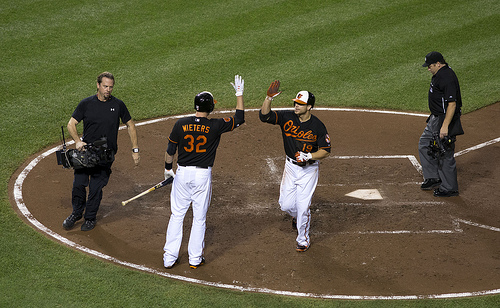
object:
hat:
[192, 91, 218, 112]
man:
[159, 74, 247, 269]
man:
[259, 79, 332, 252]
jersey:
[165, 109, 246, 167]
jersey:
[259, 109, 332, 163]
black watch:
[132, 146, 140, 153]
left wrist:
[130, 145, 140, 155]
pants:
[415, 115, 457, 193]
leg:
[186, 191, 209, 264]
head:
[96, 72, 114, 97]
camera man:
[56, 70, 140, 231]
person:
[61, 71, 141, 232]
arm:
[65, 99, 88, 142]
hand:
[130, 149, 144, 166]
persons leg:
[163, 195, 191, 266]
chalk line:
[406, 155, 424, 175]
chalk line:
[452, 133, 498, 157]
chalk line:
[455, 217, 497, 233]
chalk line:
[12, 106, 500, 300]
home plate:
[344, 189, 382, 199]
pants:
[278, 155, 320, 248]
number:
[194, 134, 206, 153]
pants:
[162, 165, 215, 268]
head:
[293, 91, 317, 115]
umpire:
[418, 50, 463, 196]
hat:
[418, 50, 444, 68]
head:
[192, 91, 214, 111]